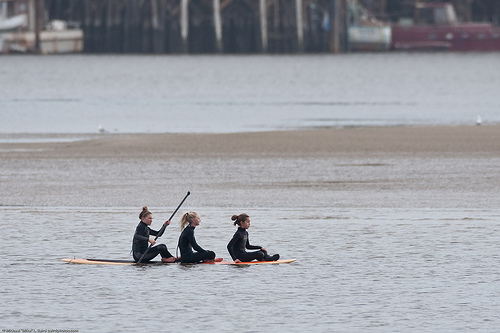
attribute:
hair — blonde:
[175, 208, 202, 228]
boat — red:
[382, 19, 494, 53]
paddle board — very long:
[65, 251, 304, 274]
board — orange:
[57, 255, 301, 270]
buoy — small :
[471, 110, 488, 134]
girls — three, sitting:
[133, 190, 281, 272]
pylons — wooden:
[24, 3, 384, 65]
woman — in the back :
[134, 208, 176, 261]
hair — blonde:
[179, 210, 197, 230]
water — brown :
[282, 209, 477, 319]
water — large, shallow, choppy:
[13, 55, 480, 331]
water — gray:
[36, 312, 77, 330]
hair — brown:
[228, 212, 249, 226]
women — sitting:
[220, 207, 274, 277]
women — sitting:
[173, 200, 234, 289]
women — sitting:
[101, 192, 223, 317]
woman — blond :
[174, 207, 220, 267]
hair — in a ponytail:
[169, 197, 208, 248]